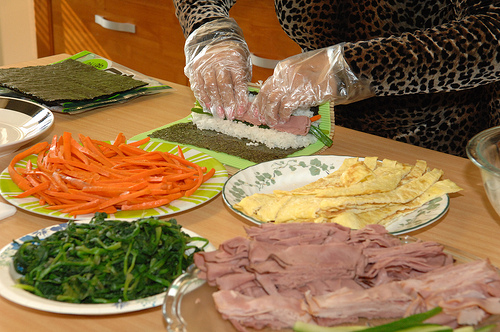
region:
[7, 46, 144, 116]
sea weed sushi wrapper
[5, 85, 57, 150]
black and white plate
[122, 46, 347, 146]
sushi roll being made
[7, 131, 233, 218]
thinly sliced carrots on a plate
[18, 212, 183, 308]
green seaweed on a plate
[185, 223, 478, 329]
plate with slices of lunch meat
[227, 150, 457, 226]
plate with scrambled eggs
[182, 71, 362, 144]
sushi rolling mat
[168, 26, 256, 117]
clear plastic food handlers gloves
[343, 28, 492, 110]
leopard print shirt sleeve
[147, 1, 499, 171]
woman making sushi rolls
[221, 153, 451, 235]
plate with ivy decor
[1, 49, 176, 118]
sushi wrappers on paper bag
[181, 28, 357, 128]
two hands wearing plastic gloves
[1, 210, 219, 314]
plate piled with sea weed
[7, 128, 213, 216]
carrot strips cut in long slivers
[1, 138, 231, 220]
plate with green and white striped rim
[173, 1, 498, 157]
blouse made with leopard skin print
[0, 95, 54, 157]
empty bowl with brown rim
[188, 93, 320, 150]
cooked rice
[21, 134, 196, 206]
pile of orange shredded carrots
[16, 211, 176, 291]
pile of sliced green peppers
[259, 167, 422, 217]
strips of yellow omelet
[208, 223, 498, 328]
strips of lunch meat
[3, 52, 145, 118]
pages of dried green seaweed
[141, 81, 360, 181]
sushi mat with sushi roll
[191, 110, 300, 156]
white sticky rice on seaweed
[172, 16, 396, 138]
hands in plastic gloves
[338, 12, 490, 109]
lady wearing a velvet leopard print shirt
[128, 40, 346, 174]
lady making sushi rolls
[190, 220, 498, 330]
cuts of meat on a plate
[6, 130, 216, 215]
sliced carrots on plate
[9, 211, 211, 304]
greens on a plate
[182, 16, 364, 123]
clear plastic gloves on hands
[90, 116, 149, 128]
a wooden table in kitchen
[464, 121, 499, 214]
a large clear bowl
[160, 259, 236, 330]
a clear plate on a table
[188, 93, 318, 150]
rice in sandwhich roll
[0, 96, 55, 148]
a porcelain plate on a table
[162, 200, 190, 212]
a green and white paper plate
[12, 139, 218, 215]
a plate of carrots.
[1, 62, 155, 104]
A bed of sea weed.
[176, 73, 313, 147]
Sushie being rolled up.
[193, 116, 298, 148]
Rice on the sushi roll.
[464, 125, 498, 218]
A glass bowl on the table.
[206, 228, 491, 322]
Deli meat on a platter.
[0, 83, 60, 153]
Awhite plate mwith black trim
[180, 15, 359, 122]
hands with pair of gloves.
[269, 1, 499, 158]
A leopard print shirt.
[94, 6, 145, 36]
Handle of a drawer.